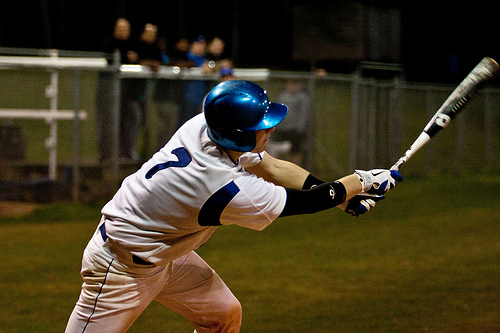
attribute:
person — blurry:
[271, 78, 306, 167]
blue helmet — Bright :
[202, 77, 287, 154]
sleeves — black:
[278, 175, 345, 216]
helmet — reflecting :
[191, 70, 292, 152]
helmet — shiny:
[207, 82, 292, 149]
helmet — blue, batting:
[186, 63, 288, 162]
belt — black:
[112, 236, 163, 279]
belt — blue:
[80, 224, 191, 263]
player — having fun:
[56, 46, 406, 331]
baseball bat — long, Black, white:
[344, 27, 494, 184]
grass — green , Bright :
[377, 219, 483, 295]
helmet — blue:
[206, 79, 285, 129]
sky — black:
[232, 17, 281, 57]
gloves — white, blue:
[342, 160, 404, 223]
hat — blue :
[206, 80, 287, 152]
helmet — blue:
[201, 78, 286, 151]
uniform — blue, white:
[58, 112, 284, 330]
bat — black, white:
[384, 58, 475, 190]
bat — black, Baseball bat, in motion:
[345, 57, 496, 216]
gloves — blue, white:
[358, 166, 405, 196]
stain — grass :
[188, 298, 235, 324]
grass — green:
[295, 239, 432, 325]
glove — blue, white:
[350, 164, 397, 196]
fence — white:
[0, 52, 483, 218]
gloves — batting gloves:
[349, 159, 406, 207]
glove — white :
[354, 167, 398, 197]